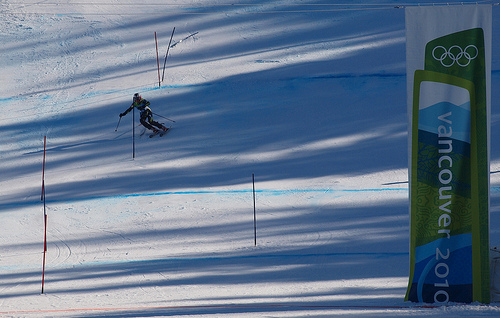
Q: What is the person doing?
A: Skiing.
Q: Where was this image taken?
A: On a mountain ski course.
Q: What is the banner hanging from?
A: A rope.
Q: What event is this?
A: Olympics.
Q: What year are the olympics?
A: 2010.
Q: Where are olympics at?
A: Vancouver.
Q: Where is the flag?
A: Side of ski slope.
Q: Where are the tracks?
A: In the snow.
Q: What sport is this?
A: Skiing.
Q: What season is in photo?
A: Winter.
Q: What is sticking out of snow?
A: Poles.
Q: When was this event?
A: 2010.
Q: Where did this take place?
A: Vancouver Canada.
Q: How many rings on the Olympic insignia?
A: Five.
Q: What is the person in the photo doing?
A: Skiing.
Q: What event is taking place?
A: Winter Olympics.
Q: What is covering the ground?
A: Snow.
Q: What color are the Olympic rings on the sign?
A: White.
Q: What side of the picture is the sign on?
A: Right.